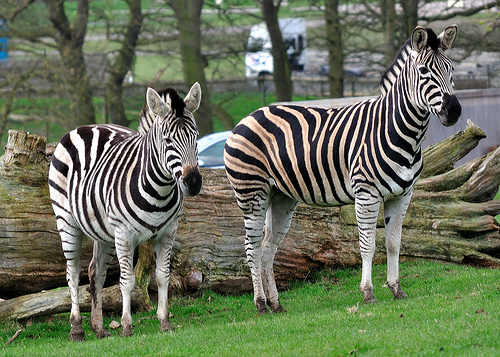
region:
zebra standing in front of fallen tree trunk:
[5, 22, 490, 339]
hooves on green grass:
[6, 245, 491, 347]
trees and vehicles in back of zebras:
[5, 5, 491, 191]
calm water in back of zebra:
[362, 25, 492, 175]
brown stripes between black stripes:
[220, 95, 385, 205]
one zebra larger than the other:
[45, 21, 461, 341]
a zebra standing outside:
[53, 74, 235, 351]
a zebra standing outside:
[211, 40, 491, 293]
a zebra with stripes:
[47, 88, 257, 355]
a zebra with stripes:
[207, 37, 498, 323]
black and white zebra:
[214, 44, 496, 284]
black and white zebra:
[18, 79, 230, 351]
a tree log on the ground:
[2, 90, 497, 311]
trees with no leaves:
[7, 15, 482, 209]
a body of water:
[414, 88, 493, 140]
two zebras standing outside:
[90, 76, 495, 348]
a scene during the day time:
[2, 1, 499, 345]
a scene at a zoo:
[3, 8, 493, 353]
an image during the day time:
[5, 12, 499, 354]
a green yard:
[3, 231, 498, 355]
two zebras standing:
[10, 11, 498, 355]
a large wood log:
[2, 118, 497, 315]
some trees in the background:
[5, 0, 490, 165]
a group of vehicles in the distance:
[207, 11, 498, 113]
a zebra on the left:
[26, 69, 217, 344]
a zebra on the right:
[216, 23, 498, 310]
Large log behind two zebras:
[0, 116, 499, 300]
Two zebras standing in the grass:
[0, 23, 497, 341]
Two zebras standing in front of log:
[1, 23, 497, 340]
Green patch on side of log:
[6, 170, 46, 273]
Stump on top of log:
[3, 128, 48, 166]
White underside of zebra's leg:
[261, 197, 298, 311]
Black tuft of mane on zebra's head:
[427, 25, 441, 49]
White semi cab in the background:
[244, 18, 311, 90]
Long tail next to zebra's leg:
[84, 238, 97, 303]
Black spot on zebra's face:
[440, 90, 460, 112]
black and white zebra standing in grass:
[222, 26, 462, 311]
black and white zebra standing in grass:
[47, 81, 203, 343]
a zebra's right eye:
[162, 137, 176, 147]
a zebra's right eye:
[419, 64, 431, 76]